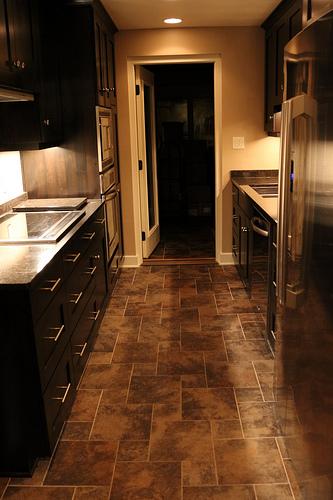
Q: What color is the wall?
A: Yellow.